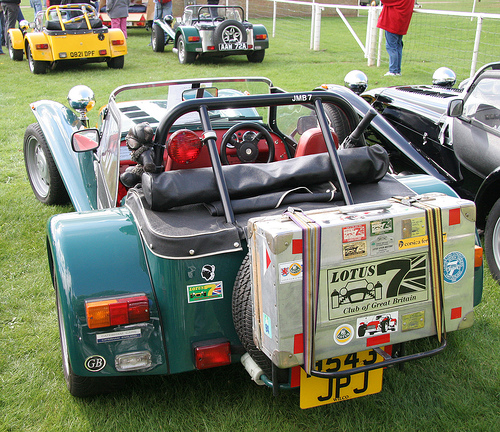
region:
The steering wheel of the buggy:
[208, 127, 278, 167]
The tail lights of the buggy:
[77, 292, 165, 326]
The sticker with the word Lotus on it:
[325, 268, 434, 313]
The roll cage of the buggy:
[131, 86, 453, 226]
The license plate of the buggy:
[302, 341, 372, 401]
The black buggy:
[337, 70, 497, 280]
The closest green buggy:
[9, 67, 496, 417]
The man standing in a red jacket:
[377, 3, 407, 81]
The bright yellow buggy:
[5, 0, 129, 70]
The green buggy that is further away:
[149, 8, 271, 66]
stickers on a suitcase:
[259, 212, 486, 346]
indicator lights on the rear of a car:
[83, 295, 154, 334]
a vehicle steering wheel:
[217, 123, 278, 172]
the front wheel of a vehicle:
[19, 123, 59, 204]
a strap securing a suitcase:
[285, 202, 326, 382]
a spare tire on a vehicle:
[222, 248, 269, 354]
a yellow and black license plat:
[295, 346, 397, 399]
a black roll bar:
[150, 87, 375, 217]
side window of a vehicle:
[90, 108, 126, 194]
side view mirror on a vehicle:
[70, 130, 102, 154]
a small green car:
[21, 73, 485, 407]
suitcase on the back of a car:
[251, 192, 477, 366]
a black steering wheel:
[217, 120, 275, 166]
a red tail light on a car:
[193, 343, 234, 367]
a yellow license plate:
[299, 353, 384, 408]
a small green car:
[151, 4, 268, 66]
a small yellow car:
[8, 4, 125, 71]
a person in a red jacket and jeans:
[378, 1, 415, 78]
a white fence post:
[308, 2, 323, 46]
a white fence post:
[269, 1, 278, 35]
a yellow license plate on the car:
[297, 346, 382, 401]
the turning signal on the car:
[85, 290, 145, 315]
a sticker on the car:
[185, 280, 221, 300]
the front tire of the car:
[20, 121, 60, 198]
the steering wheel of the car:
[219, 120, 275, 162]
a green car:
[19, 78, 484, 398]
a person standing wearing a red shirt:
[374, 2, 418, 77]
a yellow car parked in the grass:
[5, 5, 129, 69]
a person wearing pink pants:
[106, 1, 131, 38]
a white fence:
[403, 9, 499, 74]